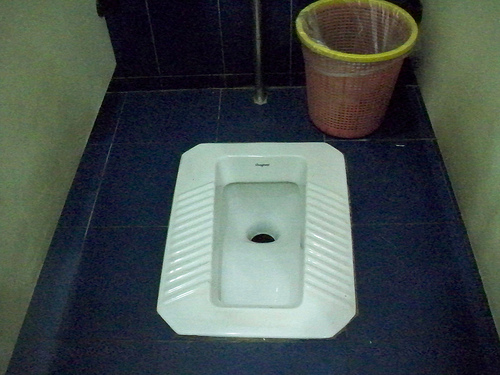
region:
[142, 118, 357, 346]
this is a toilet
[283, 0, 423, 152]
this is a dust bin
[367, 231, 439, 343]
this is a tile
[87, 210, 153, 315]
this is a tile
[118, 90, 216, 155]
this is a tile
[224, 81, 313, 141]
this is a tile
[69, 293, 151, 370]
this is a tile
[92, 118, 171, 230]
this is a tile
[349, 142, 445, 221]
this is a tile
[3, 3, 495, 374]
white green and black bathroom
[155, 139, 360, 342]
white squat toilet in a tile floor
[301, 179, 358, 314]
ridges on the side of a white toilet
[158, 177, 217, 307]
ridges on the side of a white toilet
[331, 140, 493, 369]
two black floor tiles in a bathroom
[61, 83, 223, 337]
two black floor tiles in a bathroom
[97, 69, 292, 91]
two black floor tiles in a bathroom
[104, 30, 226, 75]
two black floor tiles in a bathroom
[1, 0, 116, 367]
green painted wall in a bathroom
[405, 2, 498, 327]
green painted wall in a bathroom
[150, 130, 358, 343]
toliet on the floor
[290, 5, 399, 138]
waste basket on the floor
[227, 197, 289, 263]
water in the toliet bowl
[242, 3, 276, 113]
pipe connected to the wall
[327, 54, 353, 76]
plastic garbage bag in the waster basket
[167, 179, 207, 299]
grooves on the toliet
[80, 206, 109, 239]
white lines on the floor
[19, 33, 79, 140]
green wall around the toliet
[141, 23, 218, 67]
blue wall in back of the pole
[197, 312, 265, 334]
part of the toliet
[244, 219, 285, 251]
Small shallow dark hole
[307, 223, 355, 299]
White lined toilet pattern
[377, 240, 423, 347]
Navy blue toilet floor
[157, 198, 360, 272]
A clean spotless toilet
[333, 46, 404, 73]
Yellow and red dustbin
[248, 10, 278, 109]
Short dark black pipe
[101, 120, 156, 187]
Blue tiled checked floor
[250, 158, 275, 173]
Small writing on tile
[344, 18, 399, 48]
Polythene coated clean dustbin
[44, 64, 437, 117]
Toilet in a room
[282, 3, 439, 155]
Brown hamper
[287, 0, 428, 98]
Clear bag arond the brown hamper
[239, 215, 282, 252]
Small circle white drain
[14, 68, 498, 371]
Large blue shiny tiles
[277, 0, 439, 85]
Yellow trim around brown basket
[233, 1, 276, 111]
Silver pole in middle of floor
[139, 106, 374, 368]
White water hole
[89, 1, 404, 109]
Dark blue tiles on wall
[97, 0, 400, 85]
White grout in between blue tiles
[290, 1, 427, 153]
Brown laundry basket for clothes